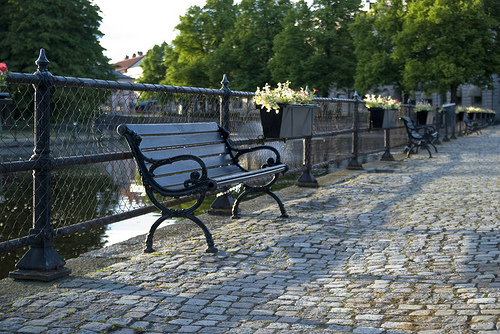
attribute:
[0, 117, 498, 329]
walkway — bricked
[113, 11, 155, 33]
sky — blue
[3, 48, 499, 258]
fence — chain link, black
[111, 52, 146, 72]
roof — red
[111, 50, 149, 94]
building — white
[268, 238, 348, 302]
ground — gray, stoned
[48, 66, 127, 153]
fence — black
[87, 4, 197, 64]
sky — clear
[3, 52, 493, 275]
fence — black, metal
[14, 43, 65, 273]
pole — black, pointed 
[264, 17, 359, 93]
leaves — green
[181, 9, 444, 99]
trees. — large, dark green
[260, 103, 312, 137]
container — gray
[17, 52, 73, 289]
post — green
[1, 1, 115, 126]
tree — tall, green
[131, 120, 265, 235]
bench — wooden, metal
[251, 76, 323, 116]
plant — gray